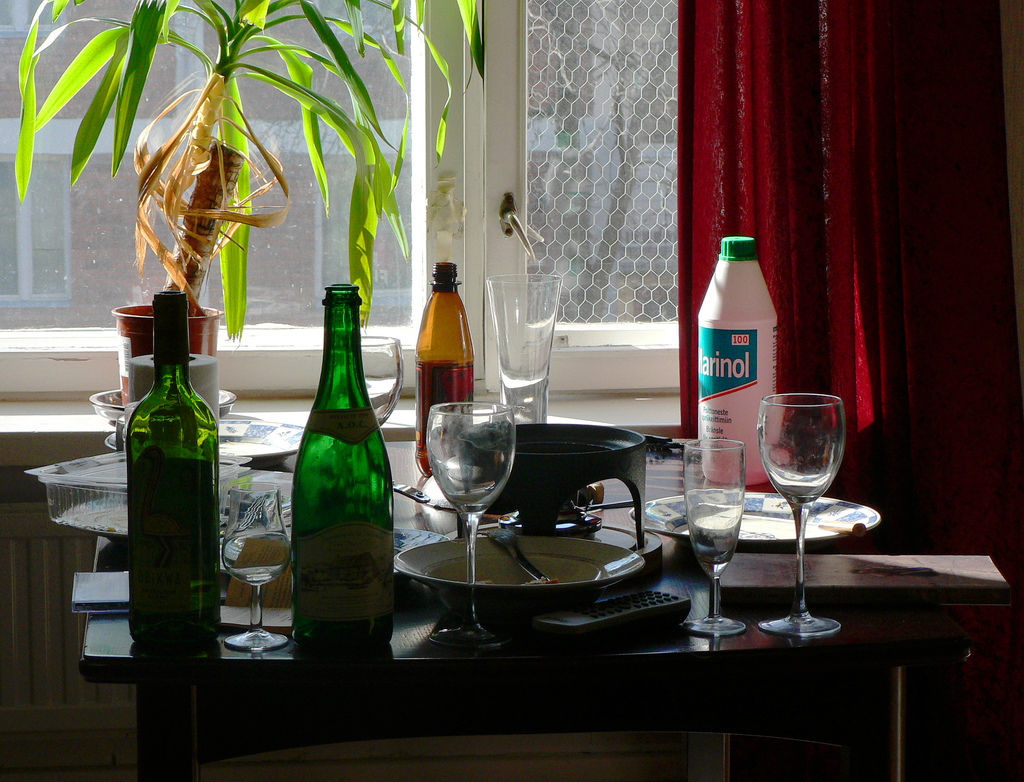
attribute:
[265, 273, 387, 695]
bottle — GREEN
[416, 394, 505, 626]
glass — WINE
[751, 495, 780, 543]
plate — WHITE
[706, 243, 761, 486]
bottle — WHITE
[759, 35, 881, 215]
curtains — RED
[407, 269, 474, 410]
bottle — BROWN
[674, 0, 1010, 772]
curtain panel — red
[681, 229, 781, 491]
bottle — white, blue, plastic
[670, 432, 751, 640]
glass — empty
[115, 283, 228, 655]
bottle — green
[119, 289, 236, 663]
bottle — green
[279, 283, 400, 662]
bottle — empty, green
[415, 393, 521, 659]
glass — empty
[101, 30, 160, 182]
leaf — long, green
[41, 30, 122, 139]
leaf — long, green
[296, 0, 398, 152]
leaf — long, green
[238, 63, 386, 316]
leaf — long, green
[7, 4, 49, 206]
leaf — long, green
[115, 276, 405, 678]
bottles — green, wine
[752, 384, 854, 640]
wine glass — empty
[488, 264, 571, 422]
glass — tall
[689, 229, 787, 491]
bottle — white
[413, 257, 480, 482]
bottle — brown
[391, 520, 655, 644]
plate — white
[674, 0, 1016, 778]
curtain — red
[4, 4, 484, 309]
tree — green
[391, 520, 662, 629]
plate — white, empty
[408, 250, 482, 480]
liquor bottle — brown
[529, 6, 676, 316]
wire — chicken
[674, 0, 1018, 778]
curtains — red